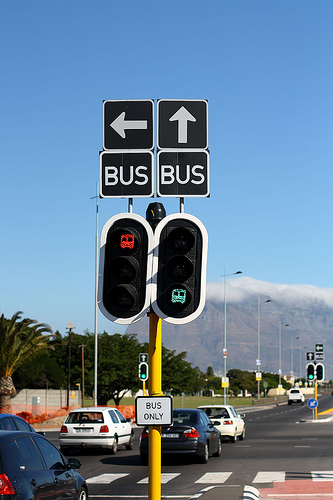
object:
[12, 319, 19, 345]
green leaves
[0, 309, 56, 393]
palm tree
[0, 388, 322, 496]
vehicles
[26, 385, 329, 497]
street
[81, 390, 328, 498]
highway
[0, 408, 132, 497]
traffic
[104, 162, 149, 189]
bus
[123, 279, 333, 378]
mountain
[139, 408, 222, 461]
car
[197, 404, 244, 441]
car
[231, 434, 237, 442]
tire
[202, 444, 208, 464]
tire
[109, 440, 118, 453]
tire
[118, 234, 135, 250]
signal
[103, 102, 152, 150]
sign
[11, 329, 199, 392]
tree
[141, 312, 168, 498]
post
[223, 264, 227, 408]
post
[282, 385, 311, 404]
white jeep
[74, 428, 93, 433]
plate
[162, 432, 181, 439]
plate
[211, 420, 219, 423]
plate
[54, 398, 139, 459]
car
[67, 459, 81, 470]
mirror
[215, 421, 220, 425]
mirror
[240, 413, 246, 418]
mirror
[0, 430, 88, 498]
car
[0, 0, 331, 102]
sky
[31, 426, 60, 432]
curb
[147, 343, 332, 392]
horizon